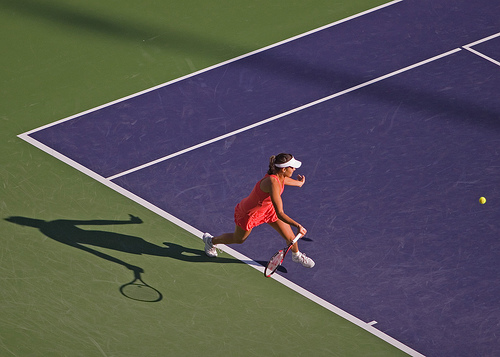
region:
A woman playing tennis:
[206, 146, 311, 276]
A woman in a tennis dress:
[217, 147, 303, 274]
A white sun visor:
[255, 145, 310, 182]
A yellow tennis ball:
[470, 185, 497, 225]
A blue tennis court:
[120, 27, 495, 343]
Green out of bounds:
[30, 222, 220, 352]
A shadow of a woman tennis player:
[0, 197, 285, 307]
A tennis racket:
[256, 215, 301, 285]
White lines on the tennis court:
[21, 62, 461, 349]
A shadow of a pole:
[65, 4, 494, 136]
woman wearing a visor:
[256, 136, 309, 187]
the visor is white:
[264, 142, 313, 179]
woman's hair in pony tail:
[266, 142, 295, 179]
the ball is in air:
[450, 178, 495, 225]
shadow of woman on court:
[0, 178, 247, 353]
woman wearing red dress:
[209, 143, 312, 270]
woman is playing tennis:
[201, 108, 338, 275]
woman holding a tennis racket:
[205, 110, 347, 282]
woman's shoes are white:
[200, 119, 347, 289]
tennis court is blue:
[53, 3, 489, 340]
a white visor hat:
[266, 150, 310, 172]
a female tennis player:
[204, 155, 344, 297]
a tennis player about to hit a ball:
[206, 148, 345, 293]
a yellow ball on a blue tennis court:
[429, 172, 499, 223]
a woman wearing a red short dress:
[234, 175, 289, 230]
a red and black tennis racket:
[258, 220, 308, 279]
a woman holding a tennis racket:
[256, 207, 313, 274]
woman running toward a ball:
[197, 140, 334, 280]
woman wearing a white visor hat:
[247, 142, 320, 191]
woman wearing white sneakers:
[200, 227, 317, 277]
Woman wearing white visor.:
[274, 142, 319, 184]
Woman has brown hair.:
[255, 136, 288, 181]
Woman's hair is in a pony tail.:
[252, 145, 293, 218]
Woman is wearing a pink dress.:
[241, 180, 288, 282]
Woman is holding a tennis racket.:
[278, 197, 318, 314]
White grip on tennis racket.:
[269, 212, 321, 284]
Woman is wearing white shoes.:
[180, 213, 341, 305]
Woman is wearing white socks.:
[191, 208, 365, 313]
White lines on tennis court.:
[343, 265, 398, 345]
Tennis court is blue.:
[334, 95, 413, 263]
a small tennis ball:
[475, 192, 488, 205]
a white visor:
[275, 154, 303, 169]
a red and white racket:
[262, 225, 309, 277]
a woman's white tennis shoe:
[200, 232, 220, 256]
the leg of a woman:
[267, 211, 296, 253]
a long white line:
[15, 132, 427, 354]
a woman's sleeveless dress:
[225, 172, 287, 228]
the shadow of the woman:
[5, 210, 289, 303]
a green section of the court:
[0, 140, 404, 355]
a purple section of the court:
[34, 49, 497, 355]